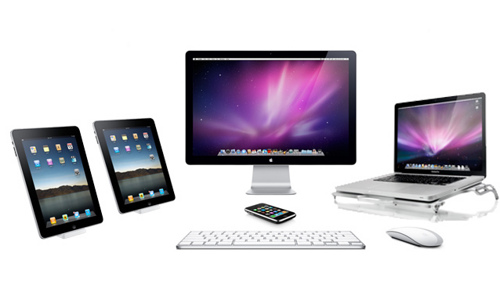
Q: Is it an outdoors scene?
A: Yes, it is outdoors.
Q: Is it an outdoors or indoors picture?
A: It is outdoors.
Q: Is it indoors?
A: No, it is outdoors.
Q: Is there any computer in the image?
A: Yes, there is a computer.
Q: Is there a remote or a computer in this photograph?
A: Yes, there is a computer.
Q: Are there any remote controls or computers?
A: Yes, there is a computer.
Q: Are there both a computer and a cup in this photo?
A: No, there is a computer but no cups.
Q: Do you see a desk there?
A: No, there are no desks.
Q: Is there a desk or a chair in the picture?
A: No, there are no desks or chairs.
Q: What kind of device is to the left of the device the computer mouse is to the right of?
A: The device is a computer.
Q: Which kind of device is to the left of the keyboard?
A: The device is a computer.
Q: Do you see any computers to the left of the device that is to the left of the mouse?
A: Yes, there is a computer to the left of the keyboard.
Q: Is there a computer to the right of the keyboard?
A: No, the computer is to the left of the keyboard.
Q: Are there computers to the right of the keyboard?
A: No, the computer is to the left of the keyboard.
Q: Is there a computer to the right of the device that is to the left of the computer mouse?
A: No, the computer is to the left of the keyboard.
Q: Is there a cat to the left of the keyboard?
A: No, there is a computer to the left of the keyboard.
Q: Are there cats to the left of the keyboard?
A: No, there is a computer to the left of the keyboard.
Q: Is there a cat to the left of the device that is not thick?
A: No, there is a computer to the left of the keyboard.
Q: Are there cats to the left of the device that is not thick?
A: No, there is a computer to the left of the keyboard.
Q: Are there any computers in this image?
A: Yes, there is a computer.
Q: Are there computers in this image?
A: Yes, there is a computer.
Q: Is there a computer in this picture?
A: Yes, there is a computer.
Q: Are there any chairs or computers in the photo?
A: Yes, there is a computer.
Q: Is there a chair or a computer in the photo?
A: Yes, there is a computer.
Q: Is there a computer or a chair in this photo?
A: Yes, there is a computer.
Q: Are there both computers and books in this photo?
A: No, there is a computer but no books.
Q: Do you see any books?
A: No, there are no books.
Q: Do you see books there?
A: No, there are no books.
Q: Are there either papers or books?
A: No, there are no books or papers.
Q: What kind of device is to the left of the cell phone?
A: The device is a computer.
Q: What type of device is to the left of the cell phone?
A: The device is a computer.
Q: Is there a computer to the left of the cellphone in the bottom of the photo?
A: Yes, there is a computer to the left of the cell phone.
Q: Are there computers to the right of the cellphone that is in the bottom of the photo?
A: No, the computer is to the left of the cell phone.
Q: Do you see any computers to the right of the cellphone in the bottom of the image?
A: No, the computer is to the left of the cell phone.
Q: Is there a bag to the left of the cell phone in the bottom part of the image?
A: No, there is a computer to the left of the mobile phone.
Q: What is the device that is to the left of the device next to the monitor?
A: The device is a computer.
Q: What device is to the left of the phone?
A: The device is a computer.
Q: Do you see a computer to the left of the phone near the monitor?
A: Yes, there is a computer to the left of the telephone.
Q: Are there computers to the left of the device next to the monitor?
A: Yes, there is a computer to the left of the telephone.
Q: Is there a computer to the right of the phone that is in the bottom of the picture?
A: No, the computer is to the left of the phone.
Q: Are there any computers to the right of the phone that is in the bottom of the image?
A: No, the computer is to the left of the phone.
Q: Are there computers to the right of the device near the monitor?
A: No, the computer is to the left of the phone.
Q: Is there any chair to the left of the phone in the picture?
A: No, there is a computer to the left of the phone.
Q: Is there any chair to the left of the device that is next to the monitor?
A: No, there is a computer to the left of the phone.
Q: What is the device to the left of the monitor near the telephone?
A: The device is a computer.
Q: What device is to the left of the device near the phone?
A: The device is a computer.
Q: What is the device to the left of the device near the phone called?
A: The device is a computer.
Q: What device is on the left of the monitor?
A: The device is a computer.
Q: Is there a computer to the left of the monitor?
A: Yes, there is a computer to the left of the monitor.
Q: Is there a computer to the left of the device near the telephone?
A: Yes, there is a computer to the left of the monitor.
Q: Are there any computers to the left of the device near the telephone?
A: Yes, there is a computer to the left of the monitor.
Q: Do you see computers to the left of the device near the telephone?
A: Yes, there is a computer to the left of the monitor.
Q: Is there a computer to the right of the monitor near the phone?
A: No, the computer is to the left of the monitor.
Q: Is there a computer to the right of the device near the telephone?
A: No, the computer is to the left of the monitor.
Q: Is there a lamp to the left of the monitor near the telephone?
A: No, there is a computer to the left of the monitor.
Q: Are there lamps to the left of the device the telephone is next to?
A: No, there is a computer to the left of the monitor.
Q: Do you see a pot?
A: No, there are no pots.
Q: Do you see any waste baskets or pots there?
A: No, there are no pots or waste baskets.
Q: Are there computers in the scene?
A: Yes, there is a computer.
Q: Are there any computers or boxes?
A: Yes, there is a computer.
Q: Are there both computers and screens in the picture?
A: Yes, there are both a computer and a screen.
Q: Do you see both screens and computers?
A: Yes, there are both a computer and a screen.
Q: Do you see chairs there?
A: No, there are no chairs.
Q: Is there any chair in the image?
A: No, there are no chairs.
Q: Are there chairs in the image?
A: No, there are no chairs.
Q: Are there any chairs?
A: No, there are no chairs.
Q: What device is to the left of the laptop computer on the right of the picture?
A: The device is a computer.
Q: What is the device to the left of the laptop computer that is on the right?
A: The device is a computer.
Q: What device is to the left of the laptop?
A: The device is a computer.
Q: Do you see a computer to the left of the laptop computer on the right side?
A: Yes, there is a computer to the left of the laptop computer.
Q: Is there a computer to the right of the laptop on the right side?
A: No, the computer is to the left of the laptop.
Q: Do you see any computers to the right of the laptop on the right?
A: No, the computer is to the left of the laptop.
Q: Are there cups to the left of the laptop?
A: No, there is a computer to the left of the laptop.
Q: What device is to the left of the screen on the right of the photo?
A: The device is a computer.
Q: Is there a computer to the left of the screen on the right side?
A: Yes, there is a computer to the left of the screen.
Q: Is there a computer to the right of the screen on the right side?
A: No, the computer is to the left of the screen.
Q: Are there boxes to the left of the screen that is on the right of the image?
A: No, there is a computer to the left of the screen.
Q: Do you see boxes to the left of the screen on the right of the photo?
A: No, there is a computer to the left of the screen.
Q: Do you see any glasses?
A: No, there are no glasses.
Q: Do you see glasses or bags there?
A: No, there are no glasses or bags.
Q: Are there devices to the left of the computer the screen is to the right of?
A: Yes, there is a device to the left of the computer.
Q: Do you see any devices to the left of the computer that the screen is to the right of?
A: Yes, there is a device to the left of the computer.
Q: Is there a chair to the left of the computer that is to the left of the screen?
A: No, there is a device to the left of the computer.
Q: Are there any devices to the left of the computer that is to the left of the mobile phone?
A: Yes, there is a device to the left of the computer.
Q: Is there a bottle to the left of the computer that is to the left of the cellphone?
A: No, there is a device to the left of the computer.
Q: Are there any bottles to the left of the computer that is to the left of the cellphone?
A: No, there is a device to the left of the computer.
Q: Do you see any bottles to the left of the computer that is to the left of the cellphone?
A: No, there is a device to the left of the computer.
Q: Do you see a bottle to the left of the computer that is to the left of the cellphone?
A: No, there is a device to the left of the computer.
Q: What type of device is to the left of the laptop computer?
A: The device is a screen.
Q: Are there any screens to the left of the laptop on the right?
A: Yes, there is a screen to the left of the laptop.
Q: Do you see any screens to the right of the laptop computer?
A: No, the screen is to the left of the laptop computer.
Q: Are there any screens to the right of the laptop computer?
A: No, the screen is to the left of the laptop computer.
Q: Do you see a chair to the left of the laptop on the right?
A: No, there is a screen to the left of the laptop.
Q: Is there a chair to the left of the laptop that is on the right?
A: No, there is a screen to the left of the laptop.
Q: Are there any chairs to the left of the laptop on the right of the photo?
A: No, there is a screen to the left of the laptop.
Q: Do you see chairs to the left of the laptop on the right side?
A: No, there is a screen to the left of the laptop.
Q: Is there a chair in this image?
A: No, there are no chairs.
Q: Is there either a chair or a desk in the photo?
A: No, there are no chairs or desks.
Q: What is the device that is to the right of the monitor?
A: The device is a screen.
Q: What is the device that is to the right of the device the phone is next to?
A: The device is a screen.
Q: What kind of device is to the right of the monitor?
A: The device is a screen.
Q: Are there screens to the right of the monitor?
A: Yes, there is a screen to the right of the monitor.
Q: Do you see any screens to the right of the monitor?
A: Yes, there is a screen to the right of the monitor.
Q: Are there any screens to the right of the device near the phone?
A: Yes, there is a screen to the right of the monitor.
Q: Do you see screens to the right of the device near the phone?
A: Yes, there is a screen to the right of the monitor.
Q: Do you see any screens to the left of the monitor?
A: No, the screen is to the right of the monitor.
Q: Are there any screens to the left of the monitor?
A: No, the screen is to the right of the monitor.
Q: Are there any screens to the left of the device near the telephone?
A: No, the screen is to the right of the monitor.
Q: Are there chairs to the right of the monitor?
A: No, there is a screen to the right of the monitor.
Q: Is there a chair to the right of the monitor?
A: No, there is a screen to the right of the monitor.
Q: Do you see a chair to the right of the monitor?
A: No, there is a screen to the right of the monitor.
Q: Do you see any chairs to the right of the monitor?
A: No, there is a screen to the right of the monitor.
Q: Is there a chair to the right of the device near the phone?
A: No, there is a screen to the right of the monitor.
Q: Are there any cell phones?
A: Yes, there is a cell phone.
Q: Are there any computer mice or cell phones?
A: Yes, there is a cell phone.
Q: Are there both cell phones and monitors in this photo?
A: Yes, there are both a cell phone and a monitor.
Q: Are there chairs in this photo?
A: No, there are no chairs.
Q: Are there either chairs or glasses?
A: No, there are no chairs or glasses.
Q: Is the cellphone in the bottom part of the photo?
A: Yes, the cellphone is in the bottom of the image.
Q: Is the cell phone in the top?
A: No, the cell phone is in the bottom of the image.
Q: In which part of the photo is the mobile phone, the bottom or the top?
A: The mobile phone is in the bottom of the image.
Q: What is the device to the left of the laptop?
A: The device is a cell phone.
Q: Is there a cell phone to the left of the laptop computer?
A: Yes, there is a cell phone to the left of the laptop computer.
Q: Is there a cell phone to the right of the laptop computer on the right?
A: No, the cell phone is to the left of the laptop.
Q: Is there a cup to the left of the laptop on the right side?
A: No, there is a cell phone to the left of the laptop.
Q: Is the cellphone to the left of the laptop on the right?
A: Yes, the cellphone is to the left of the laptop.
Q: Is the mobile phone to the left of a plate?
A: No, the mobile phone is to the left of the laptop.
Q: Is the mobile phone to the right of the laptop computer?
A: No, the mobile phone is to the left of the laptop computer.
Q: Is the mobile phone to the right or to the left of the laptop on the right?
A: The mobile phone is to the left of the laptop computer.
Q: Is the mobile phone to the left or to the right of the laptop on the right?
A: The mobile phone is to the left of the laptop computer.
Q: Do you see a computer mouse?
A: Yes, there is a computer mouse.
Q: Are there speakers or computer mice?
A: Yes, there is a computer mouse.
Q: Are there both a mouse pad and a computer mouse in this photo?
A: No, there is a computer mouse but no mouse pads.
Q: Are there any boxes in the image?
A: No, there are no boxes.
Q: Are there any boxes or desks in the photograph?
A: No, there are no boxes or desks.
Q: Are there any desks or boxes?
A: No, there are no boxes or desks.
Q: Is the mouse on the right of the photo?
A: Yes, the mouse is on the right of the image.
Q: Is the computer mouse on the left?
A: No, the computer mouse is on the right of the image.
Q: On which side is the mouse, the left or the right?
A: The mouse is on the right of the image.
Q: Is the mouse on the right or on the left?
A: The mouse is on the right of the image.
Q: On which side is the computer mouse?
A: The computer mouse is on the right of the image.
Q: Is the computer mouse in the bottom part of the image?
A: Yes, the computer mouse is in the bottom of the image.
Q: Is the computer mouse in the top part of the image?
A: No, the computer mouse is in the bottom of the image.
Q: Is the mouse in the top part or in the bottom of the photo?
A: The mouse is in the bottom of the image.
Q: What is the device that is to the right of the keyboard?
A: The device is a computer mouse.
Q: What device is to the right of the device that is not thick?
A: The device is a computer mouse.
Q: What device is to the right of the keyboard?
A: The device is a computer mouse.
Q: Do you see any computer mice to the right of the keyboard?
A: Yes, there is a computer mouse to the right of the keyboard.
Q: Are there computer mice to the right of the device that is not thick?
A: Yes, there is a computer mouse to the right of the keyboard.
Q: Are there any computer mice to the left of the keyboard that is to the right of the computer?
A: No, the computer mouse is to the right of the keyboard.